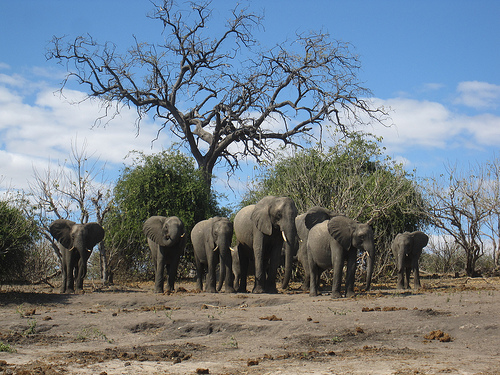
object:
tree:
[41, 0, 400, 215]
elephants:
[303, 217, 379, 298]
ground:
[0, 274, 499, 374]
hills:
[175, 314, 273, 337]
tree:
[398, 155, 500, 278]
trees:
[235, 140, 436, 283]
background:
[1, 2, 499, 285]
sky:
[0, 0, 499, 271]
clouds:
[322, 82, 500, 147]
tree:
[27, 143, 106, 270]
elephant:
[42, 217, 108, 296]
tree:
[101, 153, 229, 281]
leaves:
[383, 147, 387, 150]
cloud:
[1, 85, 175, 173]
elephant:
[228, 190, 304, 297]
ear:
[49, 218, 75, 246]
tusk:
[280, 229, 288, 242]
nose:
[74, 236, 89, 295]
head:
[67, 224, 95, 252]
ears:
[81, 222, 104, 251]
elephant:
[388, 225, 426, 291]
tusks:
[229, 245, 236, 253]